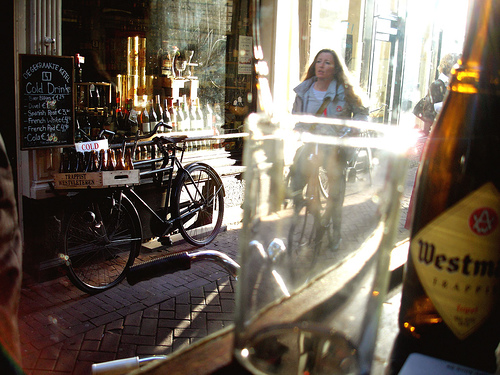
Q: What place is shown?
A: It is a sidewalk.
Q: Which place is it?
A: It is a sidewalk.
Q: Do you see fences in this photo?
A: No, there are no fences.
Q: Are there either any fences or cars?
A: No, there are no fences or cars.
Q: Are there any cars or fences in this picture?
A: No, there are no fences or cars.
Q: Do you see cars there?
A: No, there are no cars.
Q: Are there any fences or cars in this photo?
A: No, there are no cars or fences.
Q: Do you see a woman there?
A: Yes, there is a woman.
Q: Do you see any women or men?
A: Yes, there is a woman.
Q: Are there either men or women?
A: Yes, there is a woman.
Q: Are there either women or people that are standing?
A: Yes, the woman is standing.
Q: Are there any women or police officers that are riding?
A: Yes, the woman is riding.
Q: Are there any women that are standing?
A: Yes, there is a woman that is standing.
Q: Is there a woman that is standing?
A: Yes, there is a woman that is standing.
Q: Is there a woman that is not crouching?
A: Yes, there is a woman that is standing.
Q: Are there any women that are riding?
A: Yes, there is a woman that is riding.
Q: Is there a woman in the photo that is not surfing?
A: Yes, there is a woman that is riding.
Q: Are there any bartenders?
A: No, there are no bartenders.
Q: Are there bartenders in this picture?
A: No, there are no bartenders.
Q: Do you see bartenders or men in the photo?
A: No, there are no bartenders or men.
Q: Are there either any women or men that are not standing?
A: No, there is a woman but she is standing.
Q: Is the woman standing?
A: Yes, the woman is standing.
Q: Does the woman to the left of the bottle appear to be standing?
A: Yes, the woman is standing.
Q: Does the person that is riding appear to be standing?
A: Yes, the woman is standing.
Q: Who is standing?
A: The woman is standing.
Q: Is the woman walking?
A: No, the woman is standing.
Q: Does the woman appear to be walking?
A: No, the woman is standing.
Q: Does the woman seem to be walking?
A: No, the woman is standing.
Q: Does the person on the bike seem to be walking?
A: No, the woman is standing.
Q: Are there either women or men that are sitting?
A: No, there is a woman but she is standing.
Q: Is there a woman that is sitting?
A: No, there is a woman but she is standing.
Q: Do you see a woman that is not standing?
A: No, there is a woman but she is standing.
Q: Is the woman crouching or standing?
A: The woman is standing.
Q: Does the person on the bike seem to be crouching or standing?
A: The woman is standing.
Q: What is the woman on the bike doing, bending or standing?
A: The woman is standing.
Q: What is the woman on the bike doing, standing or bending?
A: The woman is standing.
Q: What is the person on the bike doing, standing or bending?
A: The woman is standing.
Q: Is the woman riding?
A: Yes, the woman is riding.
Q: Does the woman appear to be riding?
A: Yes, the woman is riding.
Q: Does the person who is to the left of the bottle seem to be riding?
A: Yes, the woman is riding.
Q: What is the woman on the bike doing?
A: The woman is riding.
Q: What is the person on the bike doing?
A: The woman is riding.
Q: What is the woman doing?
A: The woman is riding.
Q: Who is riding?
A: The woman is riding.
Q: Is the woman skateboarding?
A: No, the woman is riding.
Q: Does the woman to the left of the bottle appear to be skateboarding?
A: No, the woman is riding.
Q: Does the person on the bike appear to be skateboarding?
A: No, the woman is riding.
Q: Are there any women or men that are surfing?
A: No, there is a woman but she is riding.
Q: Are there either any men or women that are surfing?
A: No, there is a woman but she is riding.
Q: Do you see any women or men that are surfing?
A: No, there is a woman but she is riding.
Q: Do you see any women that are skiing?
A: No, there is a woman but she is riding.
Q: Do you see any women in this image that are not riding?
A: No, there is a woman but she is riding.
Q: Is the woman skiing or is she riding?
A: The woman is riding.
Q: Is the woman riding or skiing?
A: The woman is riding.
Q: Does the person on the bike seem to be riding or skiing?
A: The woman is riding.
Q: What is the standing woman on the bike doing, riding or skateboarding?
A: The woman is riding.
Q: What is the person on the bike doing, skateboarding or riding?
A: The woman is riding.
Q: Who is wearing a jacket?
A: The woman is wearing a jacket.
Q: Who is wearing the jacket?
A: The woman is wearing a jacket.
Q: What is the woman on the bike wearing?
A: The woman is wearing a jacket.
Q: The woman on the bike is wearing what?
A: The woman is wearing a jacket.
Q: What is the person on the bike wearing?
A: The woman is wearing a jacket.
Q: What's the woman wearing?
A: The woman is wearing a jacket.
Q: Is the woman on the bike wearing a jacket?
A: Yes, the woman is wearing a jacket.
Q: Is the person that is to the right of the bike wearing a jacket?
A: Yes, the woman is wearing a jacket.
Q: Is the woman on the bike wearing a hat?
A: No, the woman is wearing a jacket.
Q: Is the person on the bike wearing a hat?
A: No, the woman is wearing a jacket.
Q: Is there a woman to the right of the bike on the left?
A: Yes, there is a woman to the right of the bike.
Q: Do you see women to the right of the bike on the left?
A: Yes, there is a woman to the right of the bike.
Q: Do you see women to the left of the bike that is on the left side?
A: No, the woman is to the right of the bike.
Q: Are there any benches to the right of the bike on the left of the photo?
A: No, there is a woman to the right of the bike.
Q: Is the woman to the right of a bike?
A: Yes, the woman is to the right of a bike.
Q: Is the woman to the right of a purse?
A: No, the woman is to the right of a bike.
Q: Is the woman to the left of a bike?
A: No, the woman is to the right of a bike.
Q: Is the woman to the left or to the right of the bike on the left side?
A: The woman is to the right of the bike.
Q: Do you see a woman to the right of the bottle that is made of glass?
A: No, the woman is to the left of the bottle.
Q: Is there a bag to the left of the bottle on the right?
A: No, there is a woman to the left of the bottle.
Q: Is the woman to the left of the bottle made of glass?
A: Yes, the woman is to the left of the bottle.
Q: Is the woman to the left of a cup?
A: No, the woman is to the left of the bottle.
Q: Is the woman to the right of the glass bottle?
A: No, the woman is to the left of the bottle.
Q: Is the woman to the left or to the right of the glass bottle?
A: The woman is to the left of the bottle.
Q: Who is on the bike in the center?
A: The woman is on the bike.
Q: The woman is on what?
A: The woman is on the bike.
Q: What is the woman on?
A: The woman is on the bike.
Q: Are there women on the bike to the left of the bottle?
A: Yes, there is a woman on the bike.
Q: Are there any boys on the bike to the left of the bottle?
A: No, there is a woman on the bike.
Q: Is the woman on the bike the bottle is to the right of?
A: Yes, the woman is on the bike.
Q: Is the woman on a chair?
A: No, the woman is on the bike.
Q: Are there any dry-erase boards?
A: No, there are no dry-erase boards.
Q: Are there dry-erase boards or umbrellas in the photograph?
A: No, there are no dry-erase boards or umbrellas.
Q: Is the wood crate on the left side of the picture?
A: Yes, the crate is on the left of the image.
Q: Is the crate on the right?
A: No, the crate is on the left of the image.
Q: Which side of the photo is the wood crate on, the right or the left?
A: The crate is on the left of the image.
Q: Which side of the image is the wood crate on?
A: The crate is on the left of the image.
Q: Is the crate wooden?
A: Yes, the crate is wooden.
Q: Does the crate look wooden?
A: Yes, the crate is wooden.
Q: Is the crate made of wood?
A: Yes, the crate is made of wood.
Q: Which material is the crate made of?
A: The crate is made of wood.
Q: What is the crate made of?
A: The crate is made of wood.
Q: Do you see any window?
A: Yes, there is a window.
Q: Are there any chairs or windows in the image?
A: Yes, there is a window.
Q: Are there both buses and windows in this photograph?
A: No, there is a window but no buses.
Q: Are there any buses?
A: No, there are no buses.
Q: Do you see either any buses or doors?
A: No, there are no buses or doors.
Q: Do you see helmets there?
A: No, there are no helmets.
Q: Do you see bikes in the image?
A: Yes, there is a bike.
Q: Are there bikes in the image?
A: Yes, there is a bike.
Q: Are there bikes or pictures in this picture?
A: Yes, there is a bike.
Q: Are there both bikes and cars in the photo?
A: No, there is a bike but no cars.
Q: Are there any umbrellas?
A: No, there are no umbrellas.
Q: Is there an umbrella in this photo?
A: No, there are no umbrellas.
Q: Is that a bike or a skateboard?
A: That is a bike.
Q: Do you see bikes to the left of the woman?
A: Yes, there is a bike to the left of the woman.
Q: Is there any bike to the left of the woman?
A: Yes, there is a bike to the left of the woman.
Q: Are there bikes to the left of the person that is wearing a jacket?
A: Yes, there is a bike to the left of the woman.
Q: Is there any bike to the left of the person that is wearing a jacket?
A: Yes, there is a bike to the left of the woman.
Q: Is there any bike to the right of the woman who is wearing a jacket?
A: No, the bike is to the left of the woman.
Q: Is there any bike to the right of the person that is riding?
A: No, the bike is to the left of the woman.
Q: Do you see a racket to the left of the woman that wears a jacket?
A: No, there is a bike to the left of the woman.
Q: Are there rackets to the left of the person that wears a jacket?
A: No, there is a bike to the left of the woman.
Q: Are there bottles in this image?
A: Yes, there is a bottle.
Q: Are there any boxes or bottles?
A: Yes, there is a bottle.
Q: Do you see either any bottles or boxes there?
A: Yes, there is a bottle.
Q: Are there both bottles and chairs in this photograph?
A: No, there is a bottle but no chairs.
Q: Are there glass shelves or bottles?
A: Yes, there is a glass bottle.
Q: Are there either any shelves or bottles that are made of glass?
A: Yes, the bottle is made of glass.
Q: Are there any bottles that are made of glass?
A: Yes, there is a bottle that is made of glass.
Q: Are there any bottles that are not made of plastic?
A: Yes, there is a bottle that is made of glass.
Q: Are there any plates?
A: No, there are no plates.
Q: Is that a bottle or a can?
A: That is a bottle.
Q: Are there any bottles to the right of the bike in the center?
A: Yes, there is a bottle to the right of the bike.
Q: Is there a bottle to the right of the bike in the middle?
A: Yes, there is a bottle to the right of the bike.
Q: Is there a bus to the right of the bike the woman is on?
A: No, there is a bottle to the right of the bike.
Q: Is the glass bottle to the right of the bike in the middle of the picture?
A: Yes, the bottle is to the right of the bike.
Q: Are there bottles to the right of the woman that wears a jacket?
A: Yes, there is a bottle to the right of the woman.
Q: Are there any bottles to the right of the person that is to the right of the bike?
A: Yes, there is a bottle to the right of the woman.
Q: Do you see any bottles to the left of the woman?
A: No, the bottle is to the right of the woman.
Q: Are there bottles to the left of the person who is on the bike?
A: No, the bottle is to the right of the woman.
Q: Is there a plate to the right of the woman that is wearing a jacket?
A: No, there is a bottle to the right of the woman.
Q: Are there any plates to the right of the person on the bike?
A: No, there is a bottle to the right of the woman.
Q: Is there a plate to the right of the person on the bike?
A: No, there is a bottle to the right of the woman.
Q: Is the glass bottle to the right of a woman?
A: Yes, the bottle is to the right of a woman.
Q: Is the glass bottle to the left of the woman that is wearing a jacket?
A: No, the bottle is to the right of the woman.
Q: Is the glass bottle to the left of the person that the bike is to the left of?
A: No, the bottle is to the right of the woman.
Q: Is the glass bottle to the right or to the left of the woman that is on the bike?
A: The bottle is to the right of the woman.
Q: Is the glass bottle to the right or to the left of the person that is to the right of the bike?
A: The bottle is to the right of the woman.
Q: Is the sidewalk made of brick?
A: Yes, the sidewalk is made of brick.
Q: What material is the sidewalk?
A: The sidewalk is made of brick.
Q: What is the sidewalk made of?
A: The sidewalk is made of brick.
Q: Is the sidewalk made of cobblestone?
A: No, the sidewalk is made of brick.